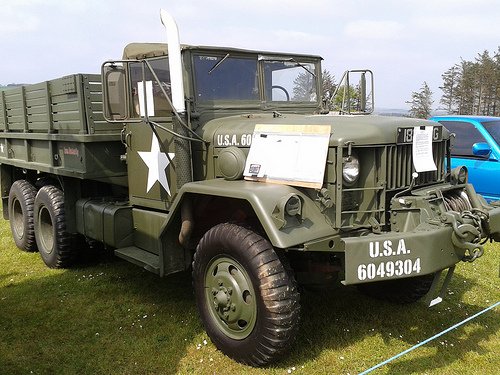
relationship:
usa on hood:
[218, 133, 239, 148] [224, 112, 429, 142]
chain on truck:
[447, 200, 486, 262] [439, 116, 500, 184]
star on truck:
[136, 134, 182, 197] [439, 116, 500, 184]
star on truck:
[139, 134, 170, 186] [439, 116, 500, 184]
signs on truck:
[245, 122, 332, 196] [439, 116, 500, 184]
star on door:
[139, 134, 170, 186] [126, 120, 192, 215]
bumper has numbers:
[354, 239, 471, 281] [359, 260, 428, 279]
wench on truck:
[447, 200, 486, 262] [439, 116, 500, 184]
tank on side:
[80, 189, 131, 223] [16, 99, 212, 222]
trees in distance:
[451, 57, 499, 113] [331, 14, 491, 97]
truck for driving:
[439, 116, 500, 184] [241, 65, 347, 165]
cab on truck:
[36, 70, 191, 187] [439, 116, 500, 184]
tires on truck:
[12, 174, 70, 221] [439, 116, 500, 184]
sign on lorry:
[245, 122, 332, 196] [0, 7, 499, 368]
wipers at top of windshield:
[196, 57, 321, 106] [192, 54, 319, 97]